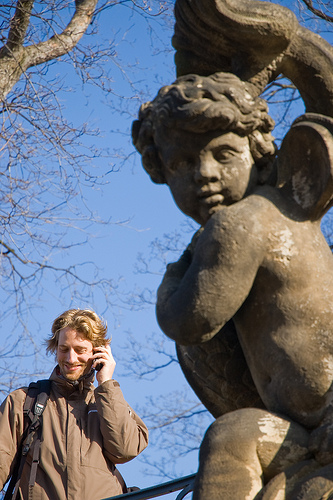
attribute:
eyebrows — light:
[57, 341, 87, 352]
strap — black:
[23, 377, 52, 498]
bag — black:
[0, 374, 52, 498]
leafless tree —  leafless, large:
[3, 0, 129, 294]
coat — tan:
[0, 365, 146, 499]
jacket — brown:
[13, 364, 133, 493]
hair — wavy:
[61, 308, 91, 328]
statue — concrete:
[127, 79, 331, 411]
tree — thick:
[1, 1, 114, 212]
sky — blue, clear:
[0, 1, 306, 497]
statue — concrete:
[109, 44, 328, 493]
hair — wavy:
[126, 72, 282, 163]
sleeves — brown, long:
[84, 380, 145, 462]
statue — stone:
[120, 1, 322, 498]